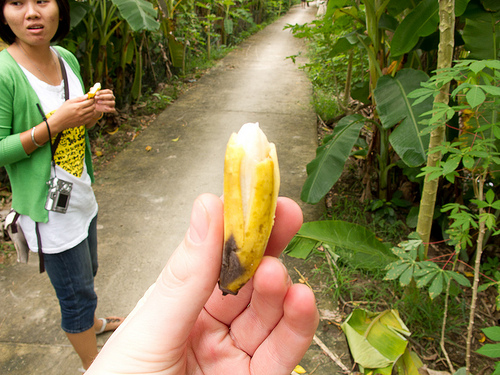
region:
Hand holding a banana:
[83, 115, 325, 372]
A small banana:
[221, 106, 275, 298]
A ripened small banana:
[214, 118, 281, 302]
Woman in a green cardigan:
[1, 5, 136, 371]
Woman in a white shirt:
[2, 3, 141, 366]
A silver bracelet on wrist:
[28, 127, 43, 149]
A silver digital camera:
[47, 174, 72, 217]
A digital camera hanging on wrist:
[35, 110, 74, 217]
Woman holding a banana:
[81, 80, 122, 120]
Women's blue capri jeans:
[23, 215, 108, 333]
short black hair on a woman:
[0, 1, 75, 47]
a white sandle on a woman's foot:
[92, 311, 124, 337]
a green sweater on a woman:
[0, 42, 95, 224]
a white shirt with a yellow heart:
[17, 48, 97, 254]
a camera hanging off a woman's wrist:
[44, 173, 80, 216]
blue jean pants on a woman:
[36, 209, 102, 339]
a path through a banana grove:
[0, 0, 352, 373]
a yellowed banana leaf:
[341, 303, 410, 370]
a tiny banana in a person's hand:
[213, 120, 280, 299]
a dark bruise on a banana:
[220, 235, 242, 289]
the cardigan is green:
[2, 54, 119, 234]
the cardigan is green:
[1, 48, 86, 180]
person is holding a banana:
[148, 117, 324, 364]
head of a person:
[3, 1, 80, 46]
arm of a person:
[0, 90, 86, 187]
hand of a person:
[55, 90, 107, 144]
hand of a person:
[83, 77, 130, 119]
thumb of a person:
[130, 185, 247, 310]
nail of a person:
[171, 204, 226, 255]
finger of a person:
[232, 196, 330, 336]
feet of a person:
[95, 298, 143, 330]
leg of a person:
[43, 241, 130, 373]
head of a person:
[0, 4, 77, 59]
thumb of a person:
[143, 184, 239, 321]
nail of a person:
[185, 195, 236, 235]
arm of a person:
[0, 102, 61, 179]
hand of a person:
[57, 80, 106, 131]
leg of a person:
[30, 237, 114, 358]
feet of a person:
[92, 302, 140, 342]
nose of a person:
[18, 4, 45, 27]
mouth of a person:
[6, 14, 67, 36]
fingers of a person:
[231, 184, 333, 349]